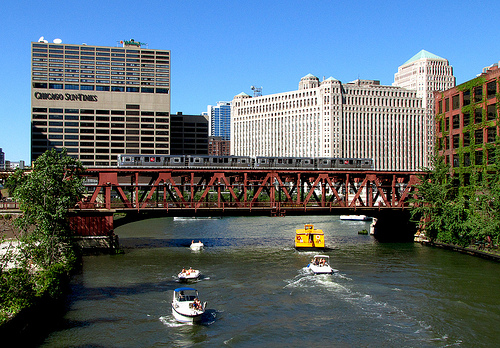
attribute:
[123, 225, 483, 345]
water — body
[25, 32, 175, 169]
building — tall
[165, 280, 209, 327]
boat — small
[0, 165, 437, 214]
bridge — red, metal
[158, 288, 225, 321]
boat — blue, white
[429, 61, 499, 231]
building — brown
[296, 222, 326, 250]
boat — yellow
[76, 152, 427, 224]
bridge — covered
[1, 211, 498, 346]
river — water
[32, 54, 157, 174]
building — Chicago Sun Times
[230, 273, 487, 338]
water — body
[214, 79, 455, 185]
building — white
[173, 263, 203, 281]
boat — small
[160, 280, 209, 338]
boat — black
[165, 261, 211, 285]
roof — white